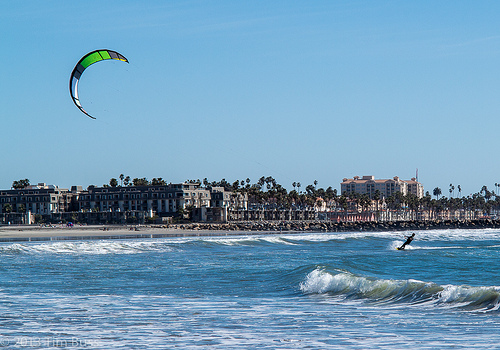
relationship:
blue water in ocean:
[21, 260, 290, 289] [1, 220, 498, 347]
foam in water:
[19, 241, 152, 259] [3, 225, 499, 342]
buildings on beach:
[2, 179, 249, 220] [0, 218, 499, 241]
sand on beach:
[9, 224, 172, 238] [2, 222, 494, 247]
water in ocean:
[3, 225, 499, 342] [1, 220, 498, 347]